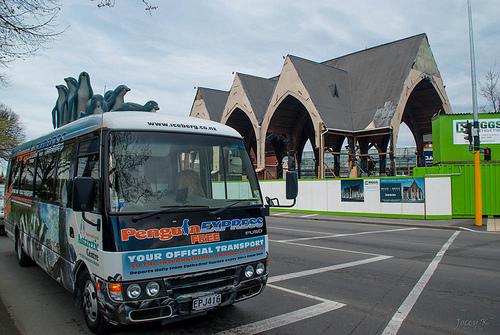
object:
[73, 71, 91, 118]
penguins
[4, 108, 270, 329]
bus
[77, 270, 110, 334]
tire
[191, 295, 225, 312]
license plate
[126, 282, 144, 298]
headlights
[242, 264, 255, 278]
headlights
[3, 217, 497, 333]
road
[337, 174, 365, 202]
sign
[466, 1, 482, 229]
pole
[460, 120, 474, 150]
traffic light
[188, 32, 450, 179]
building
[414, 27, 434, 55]
steeple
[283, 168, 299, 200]
mirror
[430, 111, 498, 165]
storage container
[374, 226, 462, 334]
lines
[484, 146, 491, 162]
crossing signal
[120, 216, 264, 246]
ad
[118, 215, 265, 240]
penguin express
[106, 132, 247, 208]
windshield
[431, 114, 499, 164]
containers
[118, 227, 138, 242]
letters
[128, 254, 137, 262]
letters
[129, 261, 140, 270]
red letters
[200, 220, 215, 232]
letters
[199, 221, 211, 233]
blue letters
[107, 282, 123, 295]
light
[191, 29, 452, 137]
roof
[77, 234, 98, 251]
letters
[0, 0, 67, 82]
tree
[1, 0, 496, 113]
sky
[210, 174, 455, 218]
barrier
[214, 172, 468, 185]
trim